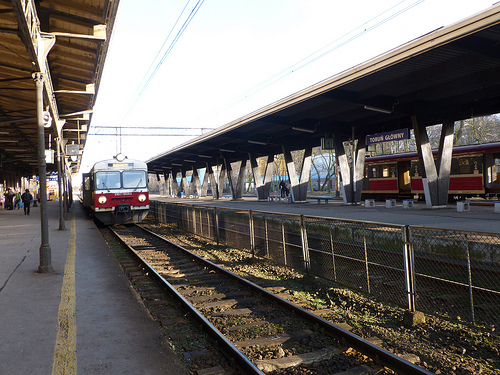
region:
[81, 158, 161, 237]
the train on the tracks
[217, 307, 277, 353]
gravel on the tracks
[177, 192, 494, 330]
the chain link fence beside the tracks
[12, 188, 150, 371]
the platform beside the train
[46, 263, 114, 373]
the line painted on the platform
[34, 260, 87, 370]
the line is yellow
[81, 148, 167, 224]
the train is red and white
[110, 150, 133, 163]
the light on the train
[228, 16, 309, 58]
the sky is blue and clear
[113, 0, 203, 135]
the power cables above the train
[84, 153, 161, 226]
train on the tracks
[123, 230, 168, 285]
track under the train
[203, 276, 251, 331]
rocks on the track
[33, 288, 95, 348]
yellow line on the ground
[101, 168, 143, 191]
window on the train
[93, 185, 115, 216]
light on the train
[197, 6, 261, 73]
sky above the train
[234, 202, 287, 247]
fence next to the train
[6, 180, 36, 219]
people next to the train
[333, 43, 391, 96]
structure above the train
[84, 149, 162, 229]
Train pulling into the station.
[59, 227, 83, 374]
Yellow line painted on the sidewalk.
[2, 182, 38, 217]
People walking around the train station.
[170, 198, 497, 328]
metal chain link fencing.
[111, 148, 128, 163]
Large headlight on the train.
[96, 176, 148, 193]
Pair of windshield wipers for rain.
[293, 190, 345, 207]
Bench for people to sit on.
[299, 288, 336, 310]
Small patch of grass growing on the ground.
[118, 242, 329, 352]
Railroad track made of steel.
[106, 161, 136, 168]
Sign showing destination of the train.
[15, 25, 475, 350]
A train is coming into the city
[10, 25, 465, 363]
The train is leaving the city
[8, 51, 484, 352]
A train is bringing passengers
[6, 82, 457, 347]
A train is carrying commuters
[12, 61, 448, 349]
A train is on the tracks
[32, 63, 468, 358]
A train is on schedule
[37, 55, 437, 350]
A train is running late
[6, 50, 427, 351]
A train is going to the suburbs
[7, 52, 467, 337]
The train belongs to the city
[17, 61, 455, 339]
The city operates this train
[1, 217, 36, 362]
The sidewalk is made of concrete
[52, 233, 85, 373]
The line on the sidewalk is yellow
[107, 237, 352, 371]
The train track is made of steel and wood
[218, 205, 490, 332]
The fence is made of metal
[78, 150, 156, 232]
The train is moving forward on the track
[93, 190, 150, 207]
The headlights on the train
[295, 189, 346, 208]
The bench in the terminal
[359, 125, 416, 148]
The sign at the bus terminal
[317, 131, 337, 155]
A clock at the terminal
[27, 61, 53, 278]
The pole is made of metal